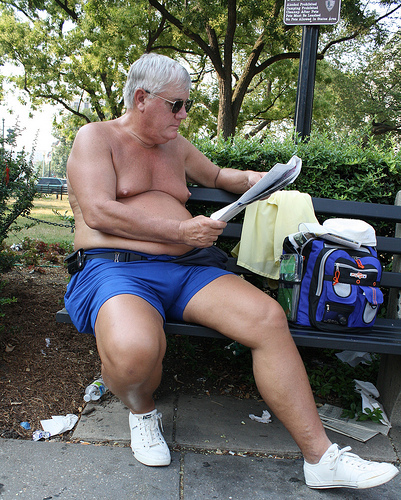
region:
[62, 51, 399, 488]
Man is sitting on park bench.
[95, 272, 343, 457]
Man's legs are clean shaven.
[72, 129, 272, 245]
Man's arms are clean shaven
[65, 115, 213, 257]
Man's chest is clean shaven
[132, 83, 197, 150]
Man's face is clean shaven.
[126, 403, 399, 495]
Man is wearing white tennis shoes.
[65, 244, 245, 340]
Man is wearing blue shorts.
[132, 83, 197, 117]
Man is wearing sunglasses.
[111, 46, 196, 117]
Man's hair is white.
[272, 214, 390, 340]
Carry-on bag sitting on bench.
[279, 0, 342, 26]
The brown sign on top of the pole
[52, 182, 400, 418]
The bench the man is sitting on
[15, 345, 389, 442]
The trash under the bench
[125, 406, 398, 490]
The white shoes the man is wearing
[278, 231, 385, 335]
The blue backpack on the bench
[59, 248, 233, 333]
The blue shorts worn by the man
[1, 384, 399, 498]
The concrete in front of the man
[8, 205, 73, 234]
The chain hanging in the background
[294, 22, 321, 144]
The pole holding the brown sign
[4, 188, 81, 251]
The grass field behind the bench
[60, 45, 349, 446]
shirtless man on bench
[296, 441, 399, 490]
white sneaker on foot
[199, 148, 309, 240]
newspaper in man's hand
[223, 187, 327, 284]
yellow shirt draped over back of bench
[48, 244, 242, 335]
blue shorts with black fanny pack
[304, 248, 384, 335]
blue bag with pockets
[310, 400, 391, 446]
newspaper on the ground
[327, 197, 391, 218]
blue wood on back of bench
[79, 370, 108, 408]
water bottle on the ground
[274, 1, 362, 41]
sign on metal pole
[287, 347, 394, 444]
litter beneath the park bench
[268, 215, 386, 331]
a small case of possessions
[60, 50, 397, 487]
a man in blue shorts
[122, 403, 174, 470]
a very white shoe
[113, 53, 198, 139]
a man wearing sunglasses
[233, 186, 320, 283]
a shirt on a bench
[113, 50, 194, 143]
a man with his hair combed forward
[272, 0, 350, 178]
a signpost and a sign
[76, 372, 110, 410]
a discarded water bottle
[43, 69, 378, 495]
an overweight man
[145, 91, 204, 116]
A PAIR OF SUNGLASSES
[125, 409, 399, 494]
A PAIR OF WHITE SNEAKERS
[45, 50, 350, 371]
MAN READING THE PAPER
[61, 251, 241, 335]
A PAIR OF BLUE SHORTS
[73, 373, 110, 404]
A PLASTIC WATER BOTTLE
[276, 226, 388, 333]
A BLUE BAG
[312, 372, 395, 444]
PAPERS ON THE GROUND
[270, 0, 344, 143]
A SIGN IN THE PARK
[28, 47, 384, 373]
A MAN SITTING ON A BENCH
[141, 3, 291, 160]
A TREE IN THE BACKGROUND